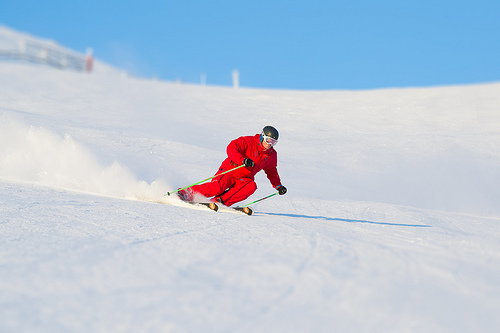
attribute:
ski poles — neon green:
[159, 160, 291, 202]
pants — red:
[188, 167, 283, 224]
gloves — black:
[238, 155, 290, 195]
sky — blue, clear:
[2, 3, 494, 88]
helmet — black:
[265, 124, 282, 141]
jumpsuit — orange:
[197, 132, 277, 201]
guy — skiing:
[177, 121, 287, 210]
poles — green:
[173, 155, 299, 219]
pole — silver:
[234, 189, 281, 219]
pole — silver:
[157, 160, 251, 197]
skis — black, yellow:
[181, 188, 263, 215]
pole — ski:
[197, 154, 267, 192]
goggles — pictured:
[260, 134, 277, 147]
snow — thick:
[0, 198, 500, 330]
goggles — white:
[259, 127, 277, 145]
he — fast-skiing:
[191, 129, 385, 273]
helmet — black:
[259, 121, 281, 136]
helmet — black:
[259, 124, 281, 143]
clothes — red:
[178, 135, 281, 212]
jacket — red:
[220, 134, 282, 189]